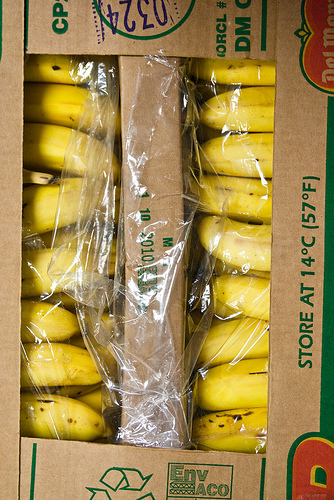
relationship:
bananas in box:
[61, 169, 232, 420] [0, 0, 334, 498]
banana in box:
[193, 269, 273, 324] [0, 1, 327, 494]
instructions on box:
[279, 163, 320, 376] [4, 30, 315, 497]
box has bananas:
[253, 47, 325, 497] [199, 62, 272, 448]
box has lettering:
[264, 81, 333, 498] [298, 166, 319, 371]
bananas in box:
[24, 55, 110, 435] [1, 51, 25, 490]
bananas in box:
[199, 62, 272, 448] [122, 47, 194, 450]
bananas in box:
[24, 55, 110, 435] [272, 27, 331, 411]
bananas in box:
[199, 62, 272, 448] [270, 32, 331, 495]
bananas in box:
[205, 65, 267, 450] [269, 103, 330, 497]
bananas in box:
[28, 54, 106, 439] [12, 432, 333, 495]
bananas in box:
[199, 62, 272, 448] [1, 437, 332, 498]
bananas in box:
[24, 55, 110, 435] [270, 32, 331, 495]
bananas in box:
[193, 54, 264, 449] [266, 62, 328, 496]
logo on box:
[284, 25, 328, 88] [287, 107, 331, 167]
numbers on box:
[87, 5, 164, 32] [186, 30, 205, 46]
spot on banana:
[205, 413, 255, 430] [191, 408, 270, 445]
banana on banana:
[196, 131, 276, 178] [203, 87, 253, 278]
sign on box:
[83, 469, 153, 493] [46, 461, 90, 490]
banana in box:
[185, 402, 262, 436] [274, 381, 305, 411]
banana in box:
[209, 370, 249, 396] [288, 395, 305, 418]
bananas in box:
[19, 391, 107, 439] [42, 449, 78, 478]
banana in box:
[25, 342, 101, 379] [46, 459, 64, 488]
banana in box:
[25, 305, 69, 327] [25, 453, 81, 483]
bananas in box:
[196, 175, 274, 222] [284, 127, 318, 157]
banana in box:
[206, 136, 267, 171] [276, 115, 314, 144]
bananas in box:
[61, 142, 223, 315] [286, 127, 312, 159]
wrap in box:
[88, 241, 207, 363] [286, 96, 320, 130]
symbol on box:
[72, 458, 122, 498] [25, 459, 82, 476]